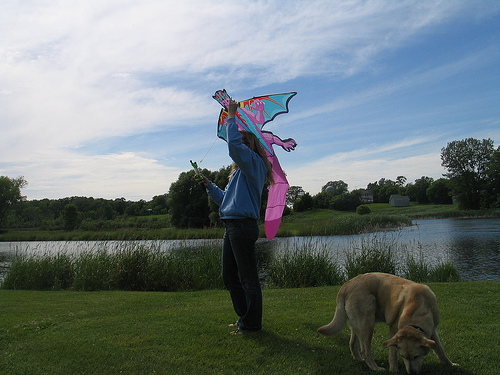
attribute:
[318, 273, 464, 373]
lab — brown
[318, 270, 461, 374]
dog — brown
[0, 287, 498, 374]
grass — trimmed, riverbanks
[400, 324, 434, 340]
collar — black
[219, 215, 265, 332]
pants — black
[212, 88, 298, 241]
kite — blue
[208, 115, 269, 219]
shirt — blue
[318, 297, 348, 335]
tail — brown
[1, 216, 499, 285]
water — calm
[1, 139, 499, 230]
trees — distant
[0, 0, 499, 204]
sky — blue, cloudy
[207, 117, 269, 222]
sweater — blue